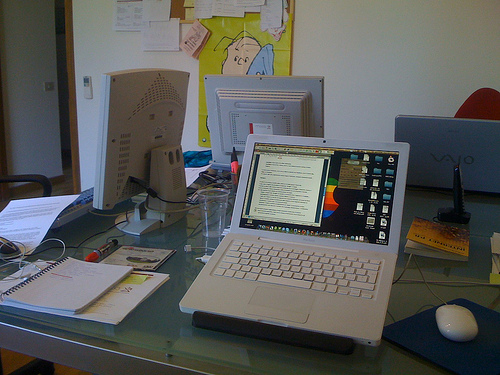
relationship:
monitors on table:
[93, 71, 331, 214] [5, 174, 490, 360]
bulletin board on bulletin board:
[112, 0, 288, 59] [99, 0, 306, 54]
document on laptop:
[254, 148, 321, 227] [218, 132, 408, 351]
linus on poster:
[220, 39, 272, 89] [200, 10, 287, 144]